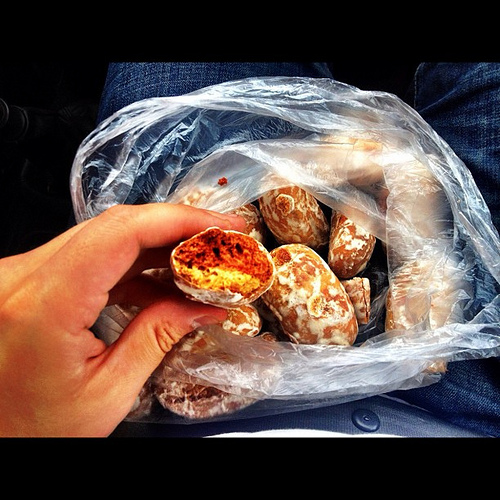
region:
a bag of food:
[51, 61, 498, 424]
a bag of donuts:
[153, 101, 498, 369]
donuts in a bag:
[84, 100, 491, 398]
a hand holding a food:
[34, 141, 306, 386]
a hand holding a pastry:
[33, 187, 385, 450]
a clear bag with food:
[89, 104, 493, 360]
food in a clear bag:
[102, 140, 487, 446]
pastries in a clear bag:
[104, 104, 483, 444]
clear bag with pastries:
[107, 141, 494, 428]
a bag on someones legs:
[87, 152, 497, 397]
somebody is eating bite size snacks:
[19, 148, 466, 411]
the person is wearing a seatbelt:
[141, 377, 470, 442]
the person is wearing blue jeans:
[105, 45, 292, 89]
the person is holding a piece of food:
[36, 212, 288, 352]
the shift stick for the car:
[1, 90, 67, 182]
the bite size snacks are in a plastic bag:
[60, 80, 497, 409]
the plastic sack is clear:
[123, 105, 282, 148]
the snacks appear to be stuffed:
[188, 241, 259, 290]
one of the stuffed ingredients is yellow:
[181, 263, 255, 295]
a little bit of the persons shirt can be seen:
[201, 423, 406, 448]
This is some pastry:
[163, 213, 283, 310]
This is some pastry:
[257, 150, 334, 258]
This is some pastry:
[298, 102, 404, 187]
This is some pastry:
[386, 240, 454, 380]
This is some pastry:
[261, 239, 356, 359]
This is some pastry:
[150, 295, 275, 388]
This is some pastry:
[154, 333, 286, 435]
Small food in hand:
[140, 218, 271, 312]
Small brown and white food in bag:
[328, 192, 376, 268]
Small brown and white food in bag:
[265, 235, 354, 352]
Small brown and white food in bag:
[255, 148, 322, 240]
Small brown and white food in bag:
[380, 248, 456, 363]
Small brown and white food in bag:
[375, 180, 461, 258]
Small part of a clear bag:
[194, 81, 267, 123]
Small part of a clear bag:
[244, 65, 292, 121]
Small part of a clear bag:
[288, 67, 368, 121]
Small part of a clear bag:
[346, 87, 439, 202]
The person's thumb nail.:
[195, 312, 220, 330]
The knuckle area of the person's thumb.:
[155, 325, 178, 353]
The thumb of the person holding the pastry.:
[105, 302, 227, 399]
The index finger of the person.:
[68, 202, 224, 263]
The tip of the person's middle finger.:
[214, 203, 250, 229]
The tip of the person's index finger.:
[206, 211, 230, 230]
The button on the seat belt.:
[353, 408, 378, 428]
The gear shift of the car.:
[5, 73, 85, 193]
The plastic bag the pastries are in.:
[98, 89, 491, 402]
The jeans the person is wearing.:
[99, 62, 499, 148]